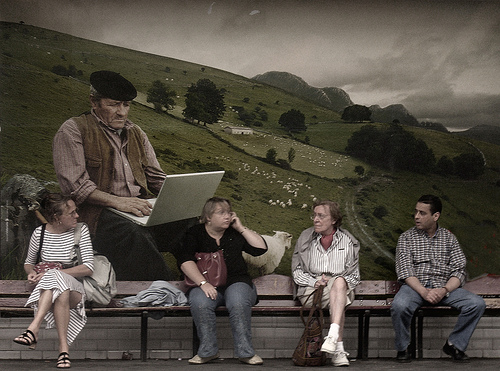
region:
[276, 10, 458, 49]
this is the sky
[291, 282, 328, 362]
this is the bag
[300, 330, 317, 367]
the bag is brown in color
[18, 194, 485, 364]
these are four people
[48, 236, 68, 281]
the dress is white in color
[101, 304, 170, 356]
this is a bench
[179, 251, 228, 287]
the woman is holding the bag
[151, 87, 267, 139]
this is the grass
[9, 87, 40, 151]
the grass is green in color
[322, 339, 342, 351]
the shoes are white in color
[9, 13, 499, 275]
Huge mural on wall behind people sitting on bench.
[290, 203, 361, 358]
Woman sitting with legs crossed.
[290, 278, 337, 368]
Woman's brown purse sitting on ground.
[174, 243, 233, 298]
Woman's brown purse under her arm.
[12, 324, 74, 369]
Woman wearing black high heel sandals.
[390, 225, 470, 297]
Man dressed in checked black and white shirt.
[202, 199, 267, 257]
Woman talking on cell phone.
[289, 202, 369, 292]
Woman wearing gray jacket over shoulders.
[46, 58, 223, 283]
Man on mural wearing black tam and typing on laptop computer.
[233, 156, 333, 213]
Sheep in background on mural.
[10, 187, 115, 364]
lady sitting on bench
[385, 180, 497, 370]
man sitting on bench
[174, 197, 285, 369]
lady holding cell phone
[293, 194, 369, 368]
lady holding brown bag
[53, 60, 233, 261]
man using laptop computer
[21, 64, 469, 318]
mural painted behind bench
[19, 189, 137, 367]
lady wearing open sandals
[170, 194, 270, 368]
lady with black shirt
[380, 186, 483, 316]
man wearing plaid shirt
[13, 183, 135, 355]
lady wearing striped dress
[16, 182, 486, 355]
four people on bench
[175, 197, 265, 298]
woman holding cell phone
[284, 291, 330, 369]
handbag on ground in front of fence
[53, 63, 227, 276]
man in picture using laptop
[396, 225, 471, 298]
plaid button down shirt on man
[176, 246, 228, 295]
purse under woman's arm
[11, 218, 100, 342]
striped dress on woman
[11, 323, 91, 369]
sandals on woman's feet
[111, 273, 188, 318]
clothing on bench seat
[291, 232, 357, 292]
striped shirt on woman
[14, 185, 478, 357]
Four people sitting on a bench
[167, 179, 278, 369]
A woman on a cell phone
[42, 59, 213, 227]
A man on a laptop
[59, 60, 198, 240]
A man wearing a black beret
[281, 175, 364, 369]
A woman faceing left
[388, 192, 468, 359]
A man faceing left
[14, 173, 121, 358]
A woman faceing right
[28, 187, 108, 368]
A woman wearing black sandles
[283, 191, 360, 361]
A woman wearing white sneakers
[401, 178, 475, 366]
A man wearing black shoes